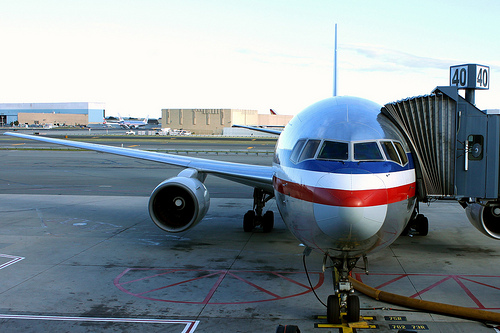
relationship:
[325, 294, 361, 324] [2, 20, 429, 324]
wheels are on front of plane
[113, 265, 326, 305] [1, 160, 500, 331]
symbol on ground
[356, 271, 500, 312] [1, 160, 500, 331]
symbol on ground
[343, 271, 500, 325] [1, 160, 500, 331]
pipe on ground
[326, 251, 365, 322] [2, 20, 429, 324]
landing gear on front of plane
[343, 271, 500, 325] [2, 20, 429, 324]
pipe connected to plane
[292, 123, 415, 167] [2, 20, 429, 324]
cockpit of plane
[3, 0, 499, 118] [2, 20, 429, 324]
sky above plane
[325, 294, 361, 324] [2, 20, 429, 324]
wheels on plane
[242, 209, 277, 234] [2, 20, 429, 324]
wheels on plane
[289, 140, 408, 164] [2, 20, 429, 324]
windows are on front of plane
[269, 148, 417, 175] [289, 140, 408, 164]
stripe around windows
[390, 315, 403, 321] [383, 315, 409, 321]
yellow lettering on black background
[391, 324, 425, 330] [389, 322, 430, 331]
yellow lettering on black background